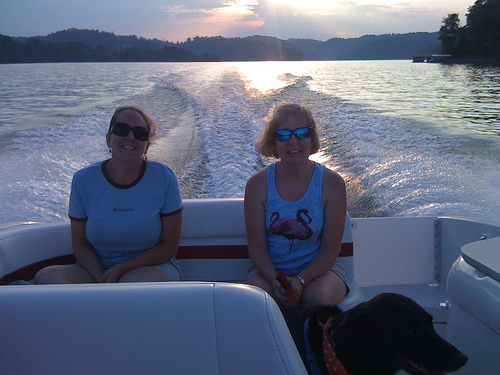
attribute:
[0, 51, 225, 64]
shore — distant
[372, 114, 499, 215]
wake — white 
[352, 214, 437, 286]
door — small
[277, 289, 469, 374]
dog — black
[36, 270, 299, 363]
seat — grey 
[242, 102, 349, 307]
two women — happy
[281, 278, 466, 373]
dog — black 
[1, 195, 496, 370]
boat — white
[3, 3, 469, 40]
clouds — white 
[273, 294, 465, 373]
dog — black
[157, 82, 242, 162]
wake — frothy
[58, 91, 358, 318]
ladies — happy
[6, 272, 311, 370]
seat — white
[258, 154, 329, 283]
shirt — light blue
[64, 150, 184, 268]
shirt — light blue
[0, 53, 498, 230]
water — calm, blue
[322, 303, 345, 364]
handkerchief — red